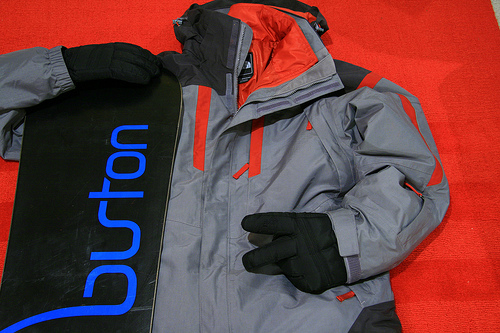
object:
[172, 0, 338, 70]
hood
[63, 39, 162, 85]
glove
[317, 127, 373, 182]
ground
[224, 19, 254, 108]
velcro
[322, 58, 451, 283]
sleeve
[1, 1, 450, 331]
gray jacket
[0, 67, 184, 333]
board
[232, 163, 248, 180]
pull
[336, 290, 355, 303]
pull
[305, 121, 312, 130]
pull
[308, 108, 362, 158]
wall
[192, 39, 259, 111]
wall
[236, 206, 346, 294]
glove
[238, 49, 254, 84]
tag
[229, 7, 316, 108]
lining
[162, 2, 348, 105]
jacket neck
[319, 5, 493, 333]
backing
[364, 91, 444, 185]
strip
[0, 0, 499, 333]
carpet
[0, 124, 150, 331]
lettering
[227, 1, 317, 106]
jacket lining